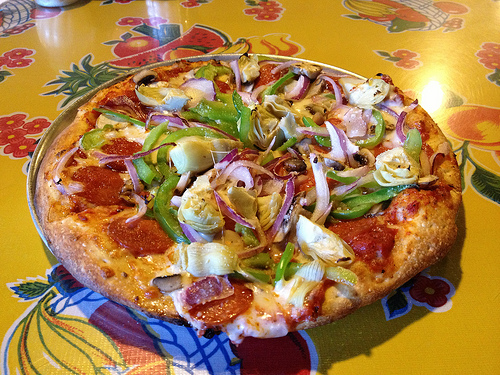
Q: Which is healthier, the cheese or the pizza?
A: The cheese is healthier than the pizza.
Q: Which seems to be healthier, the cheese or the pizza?
A: The cheese is healthier than the pizza.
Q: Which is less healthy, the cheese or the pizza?
A: The pizza is less healthy than the cheese.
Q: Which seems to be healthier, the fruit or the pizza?
A: The fruit is healthier than the pizza.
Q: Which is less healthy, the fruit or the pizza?
A: The pizza is less healthy than the fruit.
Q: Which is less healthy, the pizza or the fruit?
A: The pizza is less healthy than the fruit.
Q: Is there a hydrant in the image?
A: No, there are no fire hydrants.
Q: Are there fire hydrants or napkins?
A: No, there are no fire hydrants or napkins.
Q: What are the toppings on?
A: The toppings are on the pizza.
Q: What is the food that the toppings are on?
A: The food is a pizza.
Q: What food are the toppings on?
A: The toppings are on the pizza.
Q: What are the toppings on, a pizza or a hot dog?
A: The toppings are on a pizza.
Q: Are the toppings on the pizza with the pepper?
A: Yes, the toppings are on the pizza.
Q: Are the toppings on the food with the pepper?
A: Yes, the toppings are on the pizza.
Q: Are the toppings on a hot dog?
A: No, the toppings are on the pizza.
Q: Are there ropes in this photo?
A: No, there are no ropes.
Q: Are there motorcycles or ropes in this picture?
A: No, there are no ropes or motorcycles.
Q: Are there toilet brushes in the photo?
A: No, there are no toilet brushes.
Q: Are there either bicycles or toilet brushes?
A: No, there are no toilet brushes or bicycles.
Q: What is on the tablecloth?
A: The flower is on the tablecloth.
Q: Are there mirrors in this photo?
A: No, there are no mirrors.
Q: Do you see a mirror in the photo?
A: No, there are no mirrors.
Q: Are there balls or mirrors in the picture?
A: No, there are no mirrors or balls.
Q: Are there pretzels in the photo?
A: No, there are no pretzels.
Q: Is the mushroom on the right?
A: Yes, the mushroom is on the right of the image.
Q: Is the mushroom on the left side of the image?
A: No, the mushroom is on the right of the image.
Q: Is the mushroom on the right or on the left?
A: The mushroom is on the right of the image.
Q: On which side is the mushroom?
A: The mushroom is on the right of the image.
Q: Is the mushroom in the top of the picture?
A: Yes, the mushroom is in the top of the image.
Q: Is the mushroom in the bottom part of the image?
A: No, the mushroom is in the top of the image.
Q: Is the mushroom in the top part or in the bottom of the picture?
A: The mushroom is in the top of the image.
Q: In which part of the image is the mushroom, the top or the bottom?
A: The mushroom is in the top of the image.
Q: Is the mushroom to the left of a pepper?
A: No, the mushroom is to the right of a pepper.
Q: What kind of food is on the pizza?
A: The food is a mushroom.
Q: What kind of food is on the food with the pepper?
A: The food is a mushroom.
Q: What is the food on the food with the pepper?
A: The food is a mushroom.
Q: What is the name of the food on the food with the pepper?
A: The food is a mushroom.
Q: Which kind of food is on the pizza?
A: The food is a mushroom.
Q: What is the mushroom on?
A: The mushroom is on the pizza.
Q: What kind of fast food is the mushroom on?
A: The mushroom is on the pizza.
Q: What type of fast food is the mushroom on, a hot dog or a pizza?
A: The mushroom is on a pizza.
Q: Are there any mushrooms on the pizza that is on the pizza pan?
A: Yes, there is a mushroom on the pizza.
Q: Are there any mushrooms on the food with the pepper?
A: Yes, there is a mushroom on the pizza.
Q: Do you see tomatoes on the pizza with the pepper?
A: No, there is a mushroom on the pizza.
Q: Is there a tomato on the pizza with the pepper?
A: No, there is a mushroom on the pizza.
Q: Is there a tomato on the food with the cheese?
A: No, there is a mushroom on the pizza.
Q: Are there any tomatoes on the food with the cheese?
A: No, there is a mushroom on the pizza.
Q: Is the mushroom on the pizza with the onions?
A: Yes, the mushroom is on the pizza.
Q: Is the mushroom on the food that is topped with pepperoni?
A: Yes, the mushroom is on the pizza.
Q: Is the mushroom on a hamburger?
A: No, the mushroom is on the pizza.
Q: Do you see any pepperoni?
A: Yes, there is pepperoni.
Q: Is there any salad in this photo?
A: No, there is no salad.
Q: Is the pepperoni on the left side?
A: Yes, the pepperoni is on the left of the image.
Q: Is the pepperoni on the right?
A: No, the pepperoni is on the left of the image.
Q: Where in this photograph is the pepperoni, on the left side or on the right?
A: The pepperoni is on the left of the image.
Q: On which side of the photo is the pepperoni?
A: The pepperoni is on the left of the image.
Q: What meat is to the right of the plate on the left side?
A: The meat is pepperoni.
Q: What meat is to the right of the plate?
A: The meat is pepperoni.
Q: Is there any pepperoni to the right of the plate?
A: Yes, there is pepperoni to the right of the plate.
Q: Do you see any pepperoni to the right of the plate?
A: Yes, there is pepperoni to the right of the plate.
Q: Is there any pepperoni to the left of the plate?
A: No, the pepperoni is to the right of the plate.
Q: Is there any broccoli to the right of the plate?
A: No, there is pepperoni to the right of the plate.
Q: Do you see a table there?
A: Yes, there is a table.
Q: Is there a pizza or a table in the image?
A: Yes, there is a table.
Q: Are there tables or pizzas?
A: Yes, there is a table.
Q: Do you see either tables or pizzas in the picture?
A: Yes, there is a table.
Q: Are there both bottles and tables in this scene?
A: No, there is a table but no bottles.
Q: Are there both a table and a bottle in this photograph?
A: No, there is a table but no bottles.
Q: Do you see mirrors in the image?
A: No, there are no mirrors.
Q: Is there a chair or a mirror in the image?
A: No, there are no mirrors or chairs.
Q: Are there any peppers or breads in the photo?
A: Yes, there is a pepper.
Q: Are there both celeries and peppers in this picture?
A: No, there is a pepper but no celeries.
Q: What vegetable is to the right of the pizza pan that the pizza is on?
A: The vegetable is a pepper.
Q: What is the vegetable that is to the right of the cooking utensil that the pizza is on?
A: The vegetable is a pepper.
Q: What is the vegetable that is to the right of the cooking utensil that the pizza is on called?
A: The vegetable is a pepper.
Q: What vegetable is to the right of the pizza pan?
A: The vegetable is a pepper.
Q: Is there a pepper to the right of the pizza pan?
A: Yes, there is a pepper to the right of the pizza pan.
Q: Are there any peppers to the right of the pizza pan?
A: Yes, there is a pepper to the right of the pizza pan.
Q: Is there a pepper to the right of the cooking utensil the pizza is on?
A: Yes, there is a pepper to the right of the pizza pan.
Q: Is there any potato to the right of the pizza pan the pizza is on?
A: No, there is a pepper to the right of the pizza pan.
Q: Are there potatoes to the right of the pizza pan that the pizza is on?
A: No, there is a pepper to the right of the pizza pan.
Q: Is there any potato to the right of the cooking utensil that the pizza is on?
A: No, there is a pepper to the right of the pizza pan.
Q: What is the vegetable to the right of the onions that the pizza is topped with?
A: The vegetable is a pepper.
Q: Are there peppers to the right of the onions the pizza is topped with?
A: Yes, there is a pepper to the right of the onions.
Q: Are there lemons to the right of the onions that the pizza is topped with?
A: No, there is a pepper to the right of the onions.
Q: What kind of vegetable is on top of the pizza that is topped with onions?
A: The vegetable is a pepper.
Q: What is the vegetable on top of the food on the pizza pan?
A: The vegetable is a pepper.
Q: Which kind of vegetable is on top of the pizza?
A: The vegetable is a pepper.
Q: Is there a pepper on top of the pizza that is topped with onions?
A: Yes, there is a pepper on top of the pizza.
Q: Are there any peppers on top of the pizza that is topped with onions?
A: Yes, there is a pepper on top of the pizza.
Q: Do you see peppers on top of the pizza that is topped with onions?
A: Yes, there is a pepper on top of the pizza.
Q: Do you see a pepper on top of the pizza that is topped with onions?
A: Yes, there is a pepper on top of the pizza.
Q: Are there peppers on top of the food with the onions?
A: Yes, there is a pepper on top of the pizza.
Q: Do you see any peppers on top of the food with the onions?
A: Yes, there is a pepper on top of the pizza.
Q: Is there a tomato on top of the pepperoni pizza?
A: No, there is a pepper on top of the pizza.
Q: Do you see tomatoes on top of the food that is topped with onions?
A: No, there is a pepper on top of the pizza.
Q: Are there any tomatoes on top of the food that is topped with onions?
A: No, there is a pepper on top of the pizza.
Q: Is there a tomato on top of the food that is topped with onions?
A: No, there is a pepper on top of the pizza.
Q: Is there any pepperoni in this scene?
A: Yes, there is pepperoni.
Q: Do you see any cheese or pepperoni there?
A: Yes, there is pepperoni.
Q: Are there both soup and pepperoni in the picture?
A: No, there is pepperoni but no soup.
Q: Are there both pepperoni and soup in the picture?
A: No, there is pepperoni but no soup.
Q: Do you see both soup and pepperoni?
A: No, there is pepperoni but no soup.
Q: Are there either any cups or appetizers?
A: No, there are no cups or appetizers.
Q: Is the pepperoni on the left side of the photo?
A: Yes, the pepperoni is on the left of the image.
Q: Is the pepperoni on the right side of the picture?
A: No, the pepperoni is on the left of the image.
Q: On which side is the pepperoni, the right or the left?
A: The pepperoni is on the left of the image.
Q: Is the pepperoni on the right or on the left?
A: The pepperoni is on the left of the image.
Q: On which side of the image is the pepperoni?
A: The pepperoni is on the left of the image.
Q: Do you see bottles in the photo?
A: No, there are no bottles.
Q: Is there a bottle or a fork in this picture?
A: No, there are no bottles or forks.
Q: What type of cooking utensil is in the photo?
A: The cooking utensil is a pizza pan.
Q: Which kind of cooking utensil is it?
A: The cooking utensil is a pizza pan.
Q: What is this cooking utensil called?
A: This is a pizza pan.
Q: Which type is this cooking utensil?
A: This is a pizza pan.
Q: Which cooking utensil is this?
A: This is a pizza pan.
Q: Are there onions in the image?
A: Yes, there are onions.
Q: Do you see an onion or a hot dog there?
A: Yes, there are onions.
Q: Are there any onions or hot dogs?
A: Yes, there are onions.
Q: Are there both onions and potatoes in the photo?
A: No, there are onions but no potatoes.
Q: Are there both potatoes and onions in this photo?
A: No, there are onions but no potatoes.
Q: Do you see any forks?
A: No, there are no forks.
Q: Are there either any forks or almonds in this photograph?
A: No, there are no forks or almonds.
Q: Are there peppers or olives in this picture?
A: Yes, there is a pepper.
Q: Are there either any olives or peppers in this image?
A: Yes, there is a pepper.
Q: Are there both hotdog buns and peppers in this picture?
A: No, there is a pepper but no hotdog buns.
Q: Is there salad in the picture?
A: No, there is no salad.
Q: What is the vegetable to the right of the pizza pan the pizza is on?
A: The vegetable is a pepper.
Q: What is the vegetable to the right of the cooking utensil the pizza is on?
A: The vegetable is a pepper.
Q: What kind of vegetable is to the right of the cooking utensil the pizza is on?
A: The vegetable is a pepper.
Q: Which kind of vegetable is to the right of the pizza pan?
A: The vegetable is a pepper.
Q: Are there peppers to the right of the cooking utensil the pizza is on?
A: Yes, there is a pepper to the right of the pizza pan.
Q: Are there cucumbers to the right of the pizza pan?
A: No, there is a pepper to the right of the pizza pan.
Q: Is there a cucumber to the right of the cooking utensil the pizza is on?
A: No, there is a pepper to the right of the pizza pan.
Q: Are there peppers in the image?
A: Yes, there is a pepper.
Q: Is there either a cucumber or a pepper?
A: Yes, there is a pepper.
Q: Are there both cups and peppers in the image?
A: No, there is a pepper but no cups.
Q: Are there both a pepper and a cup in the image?
A: No, there is a pepper but no cups.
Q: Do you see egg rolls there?
A: No, there are no egg rolls.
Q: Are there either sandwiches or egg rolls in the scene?
A: No, there are no egg rolls or sandwiches.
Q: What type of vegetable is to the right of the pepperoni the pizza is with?
A: The vegetable is a pepper.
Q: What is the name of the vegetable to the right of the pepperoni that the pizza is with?
A: The vegetable is a pepper.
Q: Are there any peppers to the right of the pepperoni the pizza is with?
A: Yes, there is a pepper to the right of the pepperoni.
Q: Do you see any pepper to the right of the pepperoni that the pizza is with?
A: Yes, there is a pepper to the right of the pepperoni.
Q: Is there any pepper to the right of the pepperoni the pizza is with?
A: Yes, there is a pepper to the right of the pepperoni.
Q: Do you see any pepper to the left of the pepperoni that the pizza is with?
A: No, the pepper is to the right of the pepperoni.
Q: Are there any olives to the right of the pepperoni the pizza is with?
A: No, there is a pepper to the right of the pepperoni.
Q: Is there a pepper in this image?
A: Yes, there is a pepper.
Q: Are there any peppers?
A: Yes, there is a pepper.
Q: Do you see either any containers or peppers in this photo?
A: Yes, there is a pepper.